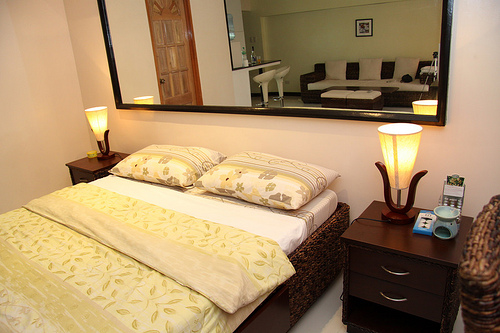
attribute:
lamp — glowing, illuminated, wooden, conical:
[383, 122, 409, 188]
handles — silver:
[387, 262, 408, 285]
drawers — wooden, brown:
[343, 126, 468, 331]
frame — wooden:
[90, 1, 449, 127]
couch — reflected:
[283, 51, 452, 114]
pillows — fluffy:
[106, 126, 348, 232]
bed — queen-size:
[0, 136, 356, 330]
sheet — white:
[93, 165, 295, 249]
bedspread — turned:
[31, 168, 287, 297]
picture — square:
[348, 13, 377, 38]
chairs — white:
[253, 62, 295, 102]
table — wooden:
[343, 168, 466, 252]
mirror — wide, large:
[126, 0, 446, 94]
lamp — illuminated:
[85, 86, 116, 156]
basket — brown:
[445, 204, 490, 308]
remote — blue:
[410, 208, 434, 247]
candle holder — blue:
[428, 215, 462, 246]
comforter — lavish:
[7, 176, 265, 332]